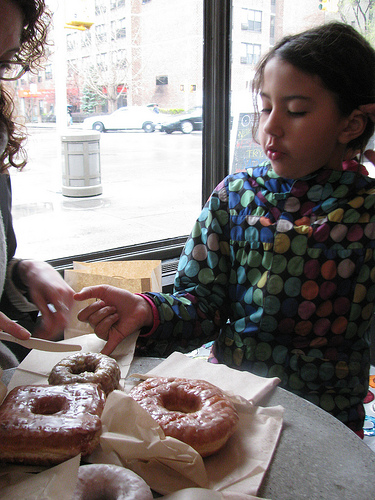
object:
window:
[9, 0, 230, 270]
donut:
[48, 352, 122, 393]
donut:
[1, 381, 105, 465]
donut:
[124, 366, 239, 458]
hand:
[72, 281, 151, 357]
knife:
[1, 331, 82, 353]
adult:
[1, 1, 75, 368]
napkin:
[136, 348, 281, 407]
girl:
[74, 22, 375, 441]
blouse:
[136, 162, 375, 441]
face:
[260, 55, 328, 179]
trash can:
[59, 133, 104, 199]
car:
[80, 104, 166, 134]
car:
[161, 111, 202, 136]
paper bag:
[62, 255, 164, 340]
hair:
[1, 1, 53, 176]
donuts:
[35, 461, 159, 500]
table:
[1, 355, 375, 500]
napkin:
[6, 327, 139, 400]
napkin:
[101, 389, 285, 495]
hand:
[0, 299, 32, 342]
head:
[252, 23, 375, 181]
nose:
[263, 110, 284, 138]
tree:
[79, 83, 102, 116]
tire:
[180, 121, 194, 136]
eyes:
[259, 98, 275, 120]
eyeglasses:
[1, 53, 31, 85]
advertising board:
[231, 110, 269, 173]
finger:
[99, 335, 120, 356]